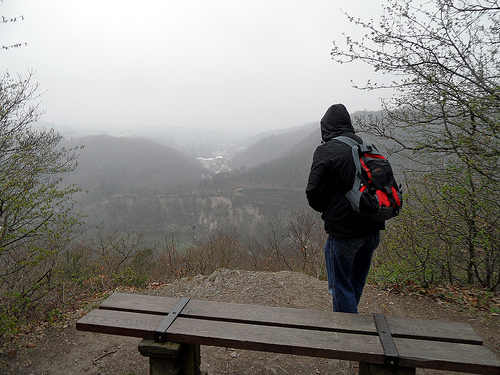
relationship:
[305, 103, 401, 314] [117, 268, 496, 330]
person standing on ledge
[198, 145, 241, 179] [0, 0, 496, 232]
town in distance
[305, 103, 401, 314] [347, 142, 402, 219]
person has backpack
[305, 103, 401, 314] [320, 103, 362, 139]
person has hood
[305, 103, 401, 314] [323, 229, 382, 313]
person has jeans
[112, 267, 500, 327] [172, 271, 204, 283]
cliff has rocks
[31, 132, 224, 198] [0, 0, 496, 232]
mountain in distance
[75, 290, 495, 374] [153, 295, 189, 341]
bench has brace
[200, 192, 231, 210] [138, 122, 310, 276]
snow in a valley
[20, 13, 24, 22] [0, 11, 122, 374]
bud on tree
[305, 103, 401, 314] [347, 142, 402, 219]
person with a backpack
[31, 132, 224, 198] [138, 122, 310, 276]
mountain and a valley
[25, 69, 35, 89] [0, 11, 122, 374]
branch of a tree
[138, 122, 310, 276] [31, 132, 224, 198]
valley of mountain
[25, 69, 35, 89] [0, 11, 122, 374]
branch of tree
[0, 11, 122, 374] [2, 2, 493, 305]
tree in fog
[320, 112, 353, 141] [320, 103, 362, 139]
head with hood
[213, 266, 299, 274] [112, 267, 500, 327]
edge of cliff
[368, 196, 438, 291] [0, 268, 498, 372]
brush on pathway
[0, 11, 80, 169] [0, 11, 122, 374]
top of tree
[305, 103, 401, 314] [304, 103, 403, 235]
person wearing jacket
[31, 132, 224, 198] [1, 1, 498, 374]
mountain in photo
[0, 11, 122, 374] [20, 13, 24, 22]
tree with bud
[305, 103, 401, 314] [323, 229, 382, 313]
person in jeans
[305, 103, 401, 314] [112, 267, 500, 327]
person standing on cliff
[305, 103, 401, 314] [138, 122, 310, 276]
person standing above valley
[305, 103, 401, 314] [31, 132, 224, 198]
person looking out at mountain